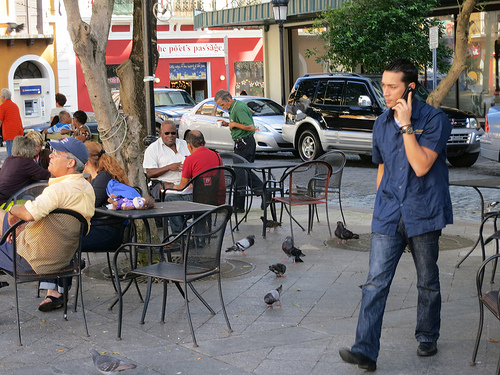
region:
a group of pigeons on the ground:
[219, 212, 362, 312]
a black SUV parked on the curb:
[277, 62, 487, 177]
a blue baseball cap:
[43, 132, 95, 170]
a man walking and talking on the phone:
[335, 55, 462, 371]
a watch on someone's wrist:
[395, 120, 420, 140]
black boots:
[333, 337, 448, 373]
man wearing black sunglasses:
[156, 121, 183, 146]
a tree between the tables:
[57, 1, 180, 267]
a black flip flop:
[33, 285, 74, 315]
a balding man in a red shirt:
[178, 127, 237, 209]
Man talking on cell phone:
[335, 57, 455, 372]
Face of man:
[379, 58, 419, 110]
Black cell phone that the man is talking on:
[398, 84, 416, 108]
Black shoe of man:
[338, 344, 378, 372]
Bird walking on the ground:
[260, 283, 285, 310]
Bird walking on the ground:
[223, 232, 258, 261]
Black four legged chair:
[111, 204, 235, 350]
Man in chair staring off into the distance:
[0, 137, 94, 349]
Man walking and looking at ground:
[213, 88, 277, 216]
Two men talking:
[142, 118, 224, 204]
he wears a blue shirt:
[371, 99, 454, 239]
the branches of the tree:
[320, 1, 434, 66]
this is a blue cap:
[49, 137, 88, 159]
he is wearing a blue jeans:
[355, 232, 440, 350]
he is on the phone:
[370, 65, 449, 253]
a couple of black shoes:
[339, 344, 441, 369]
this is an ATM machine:
[11, 59, 58, 129]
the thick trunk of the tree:
[81, 52, 129, 139]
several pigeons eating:
[236, 219, 354, 307]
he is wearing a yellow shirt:
[25, 175, 95, 272]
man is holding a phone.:
[387, 85, 413, 109]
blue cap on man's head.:
[48, 135, 90, 164]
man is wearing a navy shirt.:
[371, 103, 449, 232]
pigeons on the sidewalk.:
[228, 232, 303, 308]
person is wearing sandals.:
[37, 290, 69, 311]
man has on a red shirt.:
[181, 148, 223, 190]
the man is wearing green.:
[225, 95, 257, 142]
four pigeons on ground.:
[224, 233, 303, 308]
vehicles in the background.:
[151, 87, 483, 163]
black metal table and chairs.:
[229, 153, 349, 233]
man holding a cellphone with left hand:
[336, 60, 453, 374]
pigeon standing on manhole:
[332, 218, 362, 245]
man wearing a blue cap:
[0, 136, 96, 285]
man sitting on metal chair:
[163, 128, 227, 247]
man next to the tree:
[141, 120, 190, 246]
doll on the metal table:
[105, 191, 157, 213]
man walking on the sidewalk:
[213, 89, 277, 212]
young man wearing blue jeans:
[338, 56, 455, 373]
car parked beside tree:
[280, 71, 485, 167]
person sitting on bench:
[58, 111, 91, 149]